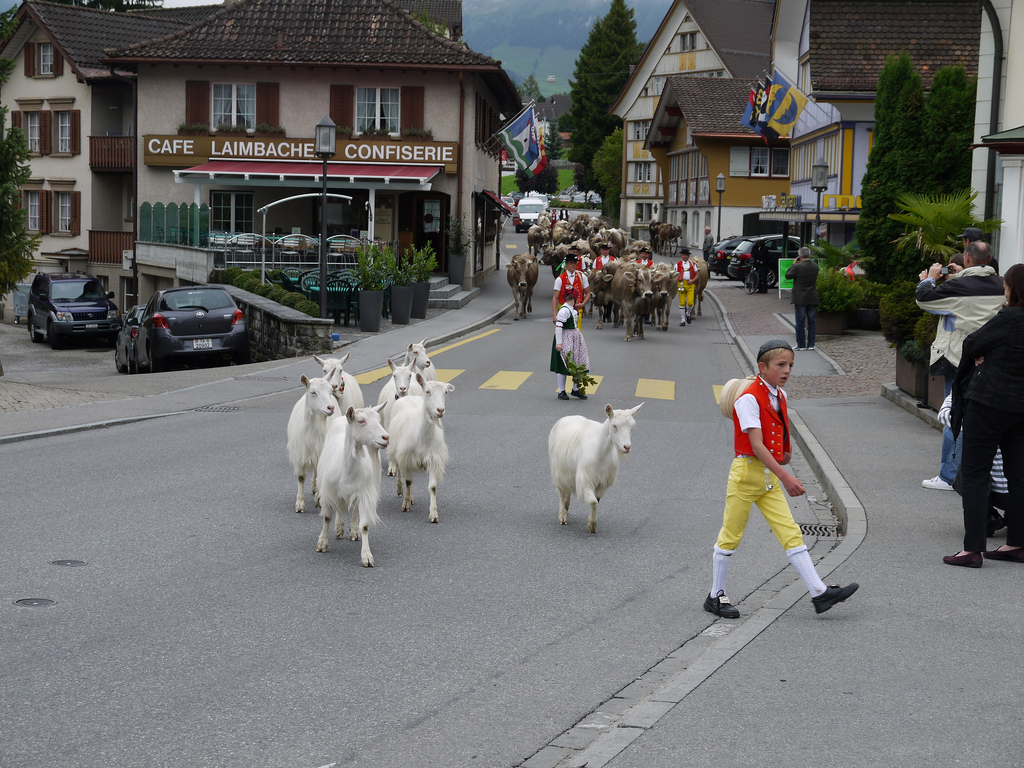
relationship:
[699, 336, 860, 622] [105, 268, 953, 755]
boy walking in street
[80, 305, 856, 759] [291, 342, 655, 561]
street under animals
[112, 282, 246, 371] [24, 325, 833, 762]
car next to street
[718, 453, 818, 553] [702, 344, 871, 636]
pants on kid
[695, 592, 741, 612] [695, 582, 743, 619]
shoe on foot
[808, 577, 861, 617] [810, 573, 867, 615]
shoe on foot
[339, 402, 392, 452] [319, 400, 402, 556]
head of animal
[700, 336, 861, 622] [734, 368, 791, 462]
boy wearing vest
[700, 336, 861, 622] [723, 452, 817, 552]
boy wearing pants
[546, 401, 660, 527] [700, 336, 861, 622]
animal behind boy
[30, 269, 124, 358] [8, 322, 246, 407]
suv down road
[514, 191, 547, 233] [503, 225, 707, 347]
van down road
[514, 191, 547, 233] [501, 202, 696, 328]
van behind cattle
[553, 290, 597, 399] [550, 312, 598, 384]
girl in dress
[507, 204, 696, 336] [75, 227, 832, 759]
cattle coming down road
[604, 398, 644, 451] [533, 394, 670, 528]
head of animal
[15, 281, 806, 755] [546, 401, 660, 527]
street next to animal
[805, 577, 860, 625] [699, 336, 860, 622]
foot of boy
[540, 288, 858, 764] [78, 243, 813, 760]
curb next to street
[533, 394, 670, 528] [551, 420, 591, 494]
animal with fur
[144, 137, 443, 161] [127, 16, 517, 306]
words on building